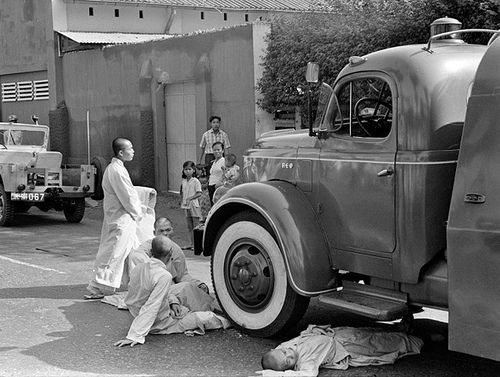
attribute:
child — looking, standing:
[176, 159, 206, 252]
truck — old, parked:
[193, 8, 499, 372]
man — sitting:
[112, 238, 236, 347]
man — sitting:
[136, 215, 211, 298]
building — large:
[1, 2, 367, 204]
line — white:
[2, 247, 71, 280]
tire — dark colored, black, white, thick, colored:
[204, 208, 308, 340]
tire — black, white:
[59, 194, 87, 226]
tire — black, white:
[0, 186, 15, 226]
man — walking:
[80, 131, 160, 302]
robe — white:
[86, 156, 156, 296]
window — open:
[324, 72, 397, 146]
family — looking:
[172, 141, 244, 254]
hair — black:
[207, 115, 222, 125]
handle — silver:
[376, 166, 394, 180]